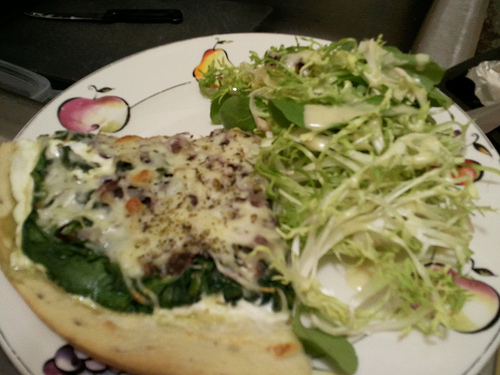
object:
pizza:
[0, 126, 311, 375]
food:
[0, 34, 500, 375]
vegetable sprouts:
[253, 113, 500, 343]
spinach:
[19, 129, 297, 316]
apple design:
[429, 133, 492, 185]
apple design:
[405, 259, 500, 333]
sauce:
[303, 103, 363, 131]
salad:
[0, 34, 500, 375]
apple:
[57, 84, 130, 133]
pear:
[193, 36, 237, 88]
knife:
[22, 9, 183, 25]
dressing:
[251, 32, 498, 343]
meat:
[170, 137, 181, 154]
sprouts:
[192, 33, 499, 344]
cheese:
[13, 129, 292, 324]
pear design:
[192, 37, 234, 88]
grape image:
[42, 344, 123, 375]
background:
[2, 1, 458, 39]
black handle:
[105, 10, 184, 25]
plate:
[0, 31, 500, 375]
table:
[0, 0, 500, 146]